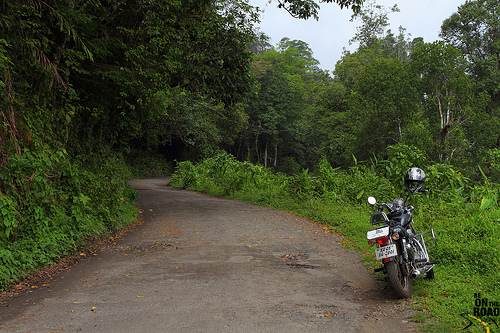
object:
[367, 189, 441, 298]
motorcycle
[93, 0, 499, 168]
woods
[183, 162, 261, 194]
green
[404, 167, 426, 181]
silver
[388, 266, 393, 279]
black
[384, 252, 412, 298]
tire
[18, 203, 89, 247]
leaves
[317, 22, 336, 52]
blue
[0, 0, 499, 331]
park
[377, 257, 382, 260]
white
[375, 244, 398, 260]
plate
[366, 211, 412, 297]
rear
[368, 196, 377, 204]
mirror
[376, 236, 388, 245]
tail lights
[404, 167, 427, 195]
helmet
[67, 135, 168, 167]
thick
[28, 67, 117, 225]
foliage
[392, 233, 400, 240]
blinker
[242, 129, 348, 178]
patch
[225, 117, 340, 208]
vegetaion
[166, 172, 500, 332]
field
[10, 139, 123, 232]
bushes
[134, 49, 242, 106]
leafy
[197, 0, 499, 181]
treeline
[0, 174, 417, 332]
pathway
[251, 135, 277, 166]
trunks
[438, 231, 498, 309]
grass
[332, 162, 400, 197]
vegetation